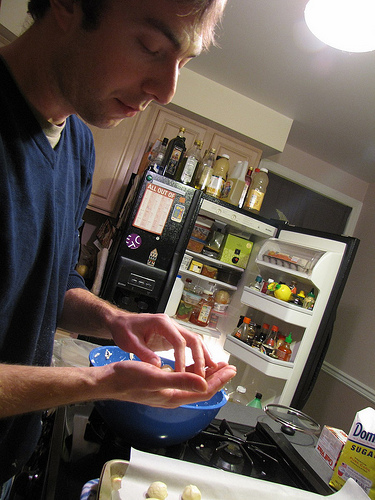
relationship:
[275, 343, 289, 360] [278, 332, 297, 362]
sauce in bottle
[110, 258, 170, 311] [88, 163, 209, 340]
ice dispencer in door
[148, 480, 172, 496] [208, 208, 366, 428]
ball in door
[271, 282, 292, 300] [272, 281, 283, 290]
ball with top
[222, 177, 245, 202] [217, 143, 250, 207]
oil in bottle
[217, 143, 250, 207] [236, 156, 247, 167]
bottle with top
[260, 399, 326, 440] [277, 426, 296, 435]
pot top with knob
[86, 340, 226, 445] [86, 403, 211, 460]
bowl on burner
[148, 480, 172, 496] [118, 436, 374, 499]
ball on paper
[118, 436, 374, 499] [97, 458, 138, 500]
paper on cookie sheet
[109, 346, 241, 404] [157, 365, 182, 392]
hand kneading dough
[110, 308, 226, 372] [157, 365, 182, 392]
hand kneading dough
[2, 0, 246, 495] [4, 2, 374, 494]
man in kitchen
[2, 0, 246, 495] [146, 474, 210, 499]
man making cookies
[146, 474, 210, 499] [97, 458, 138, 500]
balls on cookie sheet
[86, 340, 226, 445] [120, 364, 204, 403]
bowl with mixture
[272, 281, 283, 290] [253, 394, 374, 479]
top lying on counter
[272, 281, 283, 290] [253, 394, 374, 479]
top on counter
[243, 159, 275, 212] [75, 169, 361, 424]
bottle on frigerator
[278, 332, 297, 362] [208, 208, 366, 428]
bottle on door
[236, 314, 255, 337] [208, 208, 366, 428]
bottle on door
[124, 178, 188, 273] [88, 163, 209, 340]
magnets on door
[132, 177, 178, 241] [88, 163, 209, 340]
paper on door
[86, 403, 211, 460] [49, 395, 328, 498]
burner on stove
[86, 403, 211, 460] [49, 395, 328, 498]
burner top of stove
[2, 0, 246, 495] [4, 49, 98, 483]
man dressed in t-shirt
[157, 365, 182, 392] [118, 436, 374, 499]
dough on paper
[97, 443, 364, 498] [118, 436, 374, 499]
cookie sheet lined with paper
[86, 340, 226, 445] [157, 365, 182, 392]
bowl with dough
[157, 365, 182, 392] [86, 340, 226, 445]
dough in bowl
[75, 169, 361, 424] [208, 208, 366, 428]
frigerator with door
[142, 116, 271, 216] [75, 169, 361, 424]
bottles on frigerator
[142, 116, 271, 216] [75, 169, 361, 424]
bottles top of frigerator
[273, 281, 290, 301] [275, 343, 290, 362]
container contains sauce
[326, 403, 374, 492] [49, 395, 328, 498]
sugar behind stove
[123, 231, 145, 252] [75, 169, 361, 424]
magnet on frigerator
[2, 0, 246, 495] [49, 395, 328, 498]
man standing over stove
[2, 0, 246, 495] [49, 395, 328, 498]
man over stove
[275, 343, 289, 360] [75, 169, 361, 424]
sauce in frigerator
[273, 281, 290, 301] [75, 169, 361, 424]
container on top of frigerator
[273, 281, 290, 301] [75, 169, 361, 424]
container on frigerator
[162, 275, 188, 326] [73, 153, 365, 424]
milk inside frigerator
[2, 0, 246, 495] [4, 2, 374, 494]
he in kitchen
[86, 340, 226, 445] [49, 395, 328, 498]
bowl on stove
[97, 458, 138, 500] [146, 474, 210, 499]
cookie sheet has cookies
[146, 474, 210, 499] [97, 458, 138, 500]
cookies on cookie sheet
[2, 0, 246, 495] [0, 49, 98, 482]
man wearing t-shirt